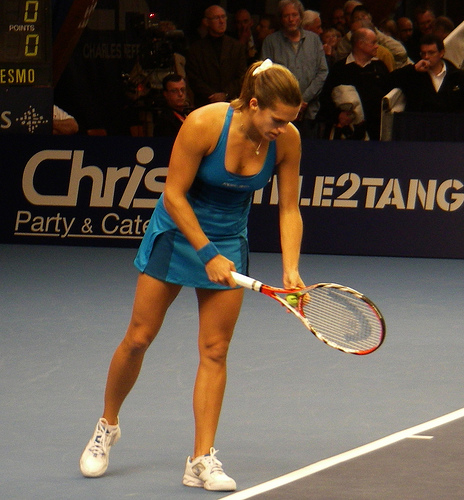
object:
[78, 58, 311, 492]
woman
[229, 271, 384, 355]
racket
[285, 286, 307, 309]
tennis ball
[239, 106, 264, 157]
necklace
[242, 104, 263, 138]
neck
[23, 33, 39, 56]
points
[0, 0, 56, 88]
scoreboard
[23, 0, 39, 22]
points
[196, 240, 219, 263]
wristband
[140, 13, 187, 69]
camera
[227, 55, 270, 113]
ponytail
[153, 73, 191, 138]
man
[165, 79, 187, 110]
face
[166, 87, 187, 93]
glasses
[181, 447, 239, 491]
sneaker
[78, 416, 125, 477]
sneaker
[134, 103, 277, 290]
outfit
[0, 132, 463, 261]
wall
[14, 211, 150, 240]
writing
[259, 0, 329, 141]
man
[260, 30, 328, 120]
shirt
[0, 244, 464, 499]
tennis court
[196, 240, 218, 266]
wrist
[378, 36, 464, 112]
man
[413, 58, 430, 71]
hand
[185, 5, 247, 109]
man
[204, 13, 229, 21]
glasses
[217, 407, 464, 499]
line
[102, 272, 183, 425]
leg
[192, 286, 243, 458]
leg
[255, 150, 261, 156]
locket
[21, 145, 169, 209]
writing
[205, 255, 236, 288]
hand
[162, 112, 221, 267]
arm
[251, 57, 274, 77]
headband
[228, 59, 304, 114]
hair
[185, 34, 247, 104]
blazer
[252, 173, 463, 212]
writing